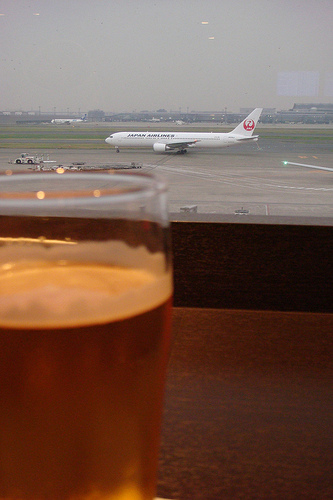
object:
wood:
[187, 307, 299, 411]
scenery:
[1, 103, 332, 131]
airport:
[1, 101, 332, 224]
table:
[1, 218, 328, 498]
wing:
[233, 107, 263, 134]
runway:
[2, 142, 330, 161]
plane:
[50, 114, 86, 125]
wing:
[237, 134, 260, 140]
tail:
[233, 108, 262, 138]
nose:
[104, 138, 107, 143]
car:
[14, 152, 34, 164]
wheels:
[116, 148, 119, 153]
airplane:
[104, 107, 264, 155]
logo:
[243, 118, 255, 131]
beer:
[0, 237, 171, 495]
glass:
[0, 169, 174, 500]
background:
[10, 14, 329, 153]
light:
[284, 161, 288, 165]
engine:
[153, 142, 166, 152]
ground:
[0, 143, 333, 226]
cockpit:
[109, 135, 113, 138]